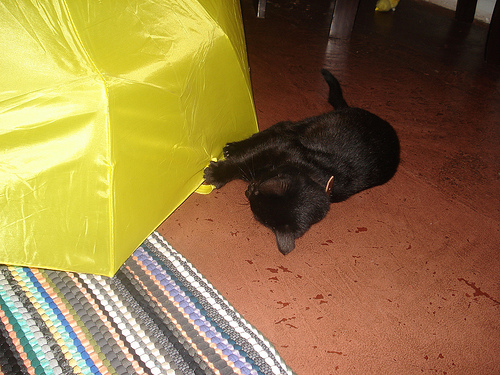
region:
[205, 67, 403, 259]
A black feline cat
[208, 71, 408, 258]
A black cat playing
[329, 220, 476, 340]
Red industrial sink floor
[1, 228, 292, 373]
Decorative woven capret flooring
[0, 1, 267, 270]
Yellow edge of umbrella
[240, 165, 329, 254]
Top of cats head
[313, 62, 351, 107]
Bottom of cats tail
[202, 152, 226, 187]
A cats open claw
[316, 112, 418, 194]
A black cats back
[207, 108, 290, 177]
A black cats paws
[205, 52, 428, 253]
this is a cat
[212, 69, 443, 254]
this cat is black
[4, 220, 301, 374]
this is a mat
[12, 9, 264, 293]
this is a yellow umbrella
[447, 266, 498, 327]
a stain on the floor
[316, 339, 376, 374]
a stain on the floor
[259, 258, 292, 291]
a stain on the floor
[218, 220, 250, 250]
a stain on the floor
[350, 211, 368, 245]
a stain on the floor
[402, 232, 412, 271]
a stain on the floor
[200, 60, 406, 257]
black cat on the floor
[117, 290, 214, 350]
colorful rug on the floor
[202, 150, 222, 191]
claws scratching the tablecloth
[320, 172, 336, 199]
tag on the cat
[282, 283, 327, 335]
spots on the floor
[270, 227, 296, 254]
ear of the cat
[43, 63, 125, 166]
shiny yellow table cloth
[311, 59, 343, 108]
tail of the cat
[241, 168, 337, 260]
head of the cat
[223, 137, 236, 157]
paw of the cat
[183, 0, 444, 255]
black cat laying on floor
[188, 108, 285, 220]
cat's paws are black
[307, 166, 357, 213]
collar around cat's neck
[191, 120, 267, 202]
cat paying with umbrella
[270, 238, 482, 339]
floor has red carpet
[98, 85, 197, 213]
umbrella sitting on floor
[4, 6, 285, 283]
yellow umbrella is open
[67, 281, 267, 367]
rug placed over carpet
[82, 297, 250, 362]
multiple stripes of various colors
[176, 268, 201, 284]
grey and white stripes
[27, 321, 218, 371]
the rug is striped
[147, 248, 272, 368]
the rug is on the floor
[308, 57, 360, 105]
the cat has a tail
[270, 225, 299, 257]
the cat has an ear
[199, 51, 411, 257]
the cat is black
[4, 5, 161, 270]
the umbrella is open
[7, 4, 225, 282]
the umbrella is yellow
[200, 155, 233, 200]
the cat has a front paw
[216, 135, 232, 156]
the back claw is out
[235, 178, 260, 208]
the cat has a nose